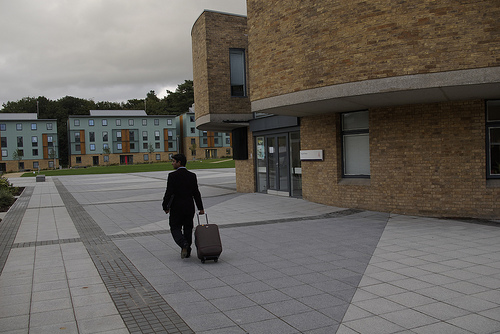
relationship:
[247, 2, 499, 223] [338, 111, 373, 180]
building has a window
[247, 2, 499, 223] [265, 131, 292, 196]
building has a door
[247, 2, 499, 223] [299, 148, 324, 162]
building has a sign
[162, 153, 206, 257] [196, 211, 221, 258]
man has luggage